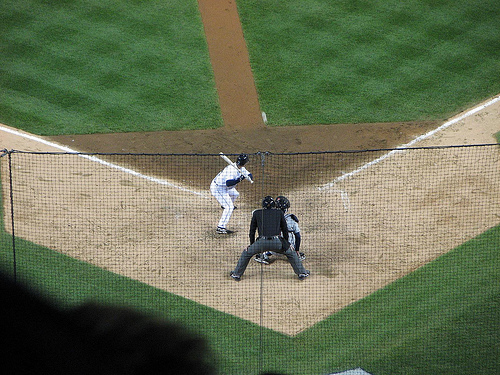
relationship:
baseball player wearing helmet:
[205, 149, 256, 235] [236, 152, 251, 164]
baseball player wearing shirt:
[205, 149, 256, 235] [215, 160, 250, 184]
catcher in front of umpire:
[256, 195, 307, 262] [231, 194, 311, 282]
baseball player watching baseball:
[205, 149, 256, 235] [262, 111, 269, 123]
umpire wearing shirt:
[231, 194, 311, 282] [249, 202, 288, 242]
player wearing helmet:
[200, 147, 253, 240] [236, 152, 251, 164]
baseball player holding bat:
[209, 145, 256, 235] [216, 152, 255, 185]